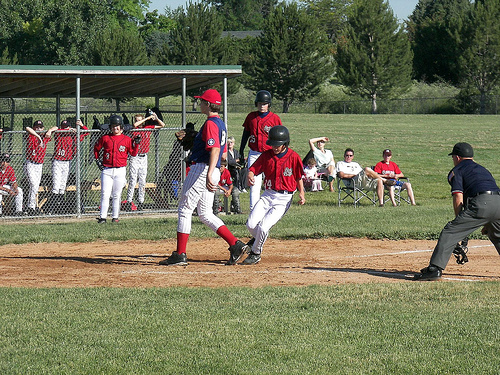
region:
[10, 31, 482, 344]
boys playing baseball game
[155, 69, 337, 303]
baseball player running to base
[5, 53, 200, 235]
team waiting in dugout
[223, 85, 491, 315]
umpire watching runner reach base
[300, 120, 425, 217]
parents sitting on sidelines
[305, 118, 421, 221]
parents' watching boys' baseball game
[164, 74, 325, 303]
red and white baseball uniforms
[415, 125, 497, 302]
blue and gray umpire uniform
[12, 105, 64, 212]
baseball player leaning on fence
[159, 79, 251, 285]
red baseball hat and socks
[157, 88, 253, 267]
Baseball player with a catchers mitt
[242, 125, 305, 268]
Baseball player running for home plate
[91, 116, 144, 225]
Baseball player in red and white uniform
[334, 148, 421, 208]
Two people sitting and watching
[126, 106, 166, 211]
Baseball player with a water bottle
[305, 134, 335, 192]
Woman and kid sitting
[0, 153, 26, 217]
Baseball player sitting on bench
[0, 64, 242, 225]
Fenced in baseball dugout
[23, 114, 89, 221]
Two baseball players holding fence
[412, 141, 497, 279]
Baseball catcher watching players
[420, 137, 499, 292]
boy wearing black shirt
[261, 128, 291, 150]
black helmet on boy's hat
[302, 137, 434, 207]
fans sitting on the chairs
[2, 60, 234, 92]
green and metal dugout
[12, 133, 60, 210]
metal fence in front of players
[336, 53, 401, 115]
green tree in the background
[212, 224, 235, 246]
red sock on boys foot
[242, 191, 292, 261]
white pants on boy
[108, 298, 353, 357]
grass green on ground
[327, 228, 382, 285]
dirt on the playing field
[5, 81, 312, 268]
baseball players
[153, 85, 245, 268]
a baseball player wearing a red baseball cap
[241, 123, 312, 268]
a player wearing a red jersey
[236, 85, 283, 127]
a player wearing a black helmet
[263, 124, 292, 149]
a black helmet the person is wearing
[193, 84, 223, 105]
a red baseball hat a player is wearing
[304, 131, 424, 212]
spectators in the background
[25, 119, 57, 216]
a person behind the fence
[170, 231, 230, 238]
red socks of a player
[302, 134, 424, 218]
spectators sitting and watching the game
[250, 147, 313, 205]
baseball player wearing red and white uniform shirt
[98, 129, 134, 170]
baseball player wearing red and white uniform shirt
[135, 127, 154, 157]
baseball player wearing red and white uniform shirt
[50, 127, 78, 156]
baseball player wearing red and white uniform shirt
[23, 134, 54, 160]
baseball player wearing red and white uniform shirt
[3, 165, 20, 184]
baseball player wearing red and white uniform shirt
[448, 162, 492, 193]
umpire wearing black uniform shirt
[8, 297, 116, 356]
short green grass on field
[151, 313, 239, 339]
short green grass on field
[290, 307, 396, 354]
short green grass on field